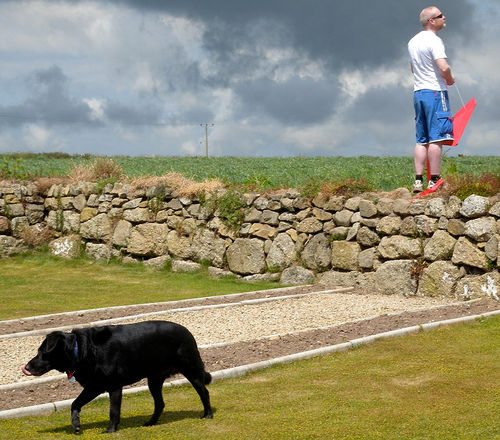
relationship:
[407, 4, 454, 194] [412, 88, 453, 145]
man inside of shorts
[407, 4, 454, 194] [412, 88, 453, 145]
man wearing shorts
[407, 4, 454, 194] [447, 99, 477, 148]
man has kite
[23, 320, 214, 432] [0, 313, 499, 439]
dog walking on grass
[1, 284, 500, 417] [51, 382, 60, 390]
walkway as stone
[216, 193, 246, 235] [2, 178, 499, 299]
plant growing on wall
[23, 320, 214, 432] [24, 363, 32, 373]
dog licking nose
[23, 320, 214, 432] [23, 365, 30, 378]
dog has tongue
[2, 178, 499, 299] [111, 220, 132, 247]
wall has stone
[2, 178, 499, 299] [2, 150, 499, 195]
wall next to field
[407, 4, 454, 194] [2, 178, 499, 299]
man standing on wall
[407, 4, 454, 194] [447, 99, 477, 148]
man holding kite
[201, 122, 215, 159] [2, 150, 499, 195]
telephone pole standing in field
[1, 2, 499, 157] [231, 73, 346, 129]
sky has cloud